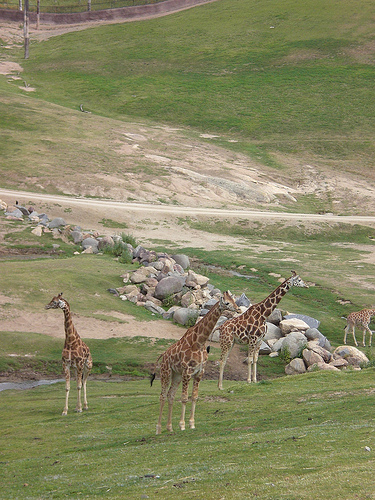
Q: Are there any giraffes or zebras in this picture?
A: Yes, there is a giraffe.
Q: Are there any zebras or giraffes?
A: Yes, there is a giraffe.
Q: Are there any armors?
A: No, there are no armors.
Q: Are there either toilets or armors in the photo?
A: No, there are no armors or toilets.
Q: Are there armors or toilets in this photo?
A: No, there are no armors or toilets.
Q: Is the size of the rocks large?
A: Yes, the rocks are large.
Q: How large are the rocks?
A: The rocks are large.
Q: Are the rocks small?
A: No, the rocks are large.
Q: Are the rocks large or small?
A: The rocks are large.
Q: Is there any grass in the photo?
A: Yes, there is grass.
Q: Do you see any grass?
A: Yes, there is grass.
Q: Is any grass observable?
A: Yes, there is grass.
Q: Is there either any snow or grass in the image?
A: Yes, there is grass.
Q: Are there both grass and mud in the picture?
A: No, there is grass but no mud.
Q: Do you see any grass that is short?
A: Yes, there is short grass.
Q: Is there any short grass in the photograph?
A: Yes, there is short grass.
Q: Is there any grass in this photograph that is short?
A: Yes, there is grass that is short.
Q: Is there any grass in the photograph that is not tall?
A: Yes, there is short grass.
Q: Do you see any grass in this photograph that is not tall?
A: Yes, there is short grass.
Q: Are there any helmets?
A: No, there are no helmets.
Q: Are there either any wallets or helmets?
A: No, there are no helmets or wallets.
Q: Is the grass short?
A: Yes, the grass is short.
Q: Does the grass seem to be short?
A: Yes, the grass is short.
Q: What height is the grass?
A: The grass is short.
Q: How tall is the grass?
A: The grass is short.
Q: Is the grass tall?
A: No, the grass is short.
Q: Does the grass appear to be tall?
A: No, the grass is short.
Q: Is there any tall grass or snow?
A: No, there is grass but it is short.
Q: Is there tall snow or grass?
A: No, there is grass but it is short.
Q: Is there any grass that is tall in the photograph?
A: No, there is grass but it is short.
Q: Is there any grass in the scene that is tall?
A: No, there is grass but it is short.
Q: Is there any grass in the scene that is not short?
A: No, there is grass but it is short.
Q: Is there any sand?
A: Yes, there is sand.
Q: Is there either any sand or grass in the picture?
A: Yes, there is sand.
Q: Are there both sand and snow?
A: No, there is sand but no snow.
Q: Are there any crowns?
A: No, there are no crowns.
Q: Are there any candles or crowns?
A: No, there are no crowns or candles.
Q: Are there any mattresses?
A: No, there are no mattresses.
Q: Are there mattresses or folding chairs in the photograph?
A: No, there are no mattresses or folding chairs.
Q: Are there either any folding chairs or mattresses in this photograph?
A: No, there are no mattresses or folding chairs.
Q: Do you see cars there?
A: No, there are no cars.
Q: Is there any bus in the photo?
A: No, there are no buses.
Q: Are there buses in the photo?
A: No, there are no buses.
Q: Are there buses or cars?
A: No, there are no buses or cars.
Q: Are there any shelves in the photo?
A: No, there are no shelves.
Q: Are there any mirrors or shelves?
A: No, there are no shelves or mirrors.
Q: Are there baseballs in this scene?
A: No, there are no baseballs.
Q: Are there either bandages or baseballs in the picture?
A: No, there are no baseballs or bandages.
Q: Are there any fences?
A: Yes, there is a fence.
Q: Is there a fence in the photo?
A: Yes, there is a fence.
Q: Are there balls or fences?
A: Yes, there is a fence.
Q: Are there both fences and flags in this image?
A: No, there is a fence but no flags.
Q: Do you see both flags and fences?
A: No, there is a fence but no flags.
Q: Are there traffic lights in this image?
A: No, there are no traffic lights.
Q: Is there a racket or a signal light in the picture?
A: No, there are no traffic lights or rackets.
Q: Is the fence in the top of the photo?
A: Yes, the fence is in the top of the image.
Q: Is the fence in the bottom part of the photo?
A: No, the fence is in the top of the image.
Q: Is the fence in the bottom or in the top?
A: The fence is in the top of the image.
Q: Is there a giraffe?
A: Yes, there is a giraffe.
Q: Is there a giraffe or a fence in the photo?
A: Yes, there is a giraffe.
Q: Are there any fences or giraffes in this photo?
A: Yes, there is a giraffe.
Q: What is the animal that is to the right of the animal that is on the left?
A: The animal is a giraffe.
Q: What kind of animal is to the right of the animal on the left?
A: The animal is a giraffe.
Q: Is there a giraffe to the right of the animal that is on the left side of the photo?
A: Yes, there is a giraffe to the right of the animal.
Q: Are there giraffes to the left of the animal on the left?
A: No, the giraffe is to the right of the animal.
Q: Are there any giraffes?
A: Yes, there is a giraffe.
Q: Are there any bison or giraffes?
A: Yes, there is a giraffe.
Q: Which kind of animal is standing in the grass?
A: The animal is a giraffe.